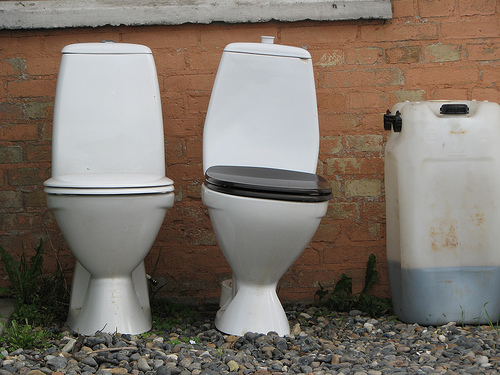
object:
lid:
[41, 173, 175, 197]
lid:
[204, 164, 336, 198]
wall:
[4, 26, 500, 270]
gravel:
[167, 331, 229, 371]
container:
[384, 95, 500, 327]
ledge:
[133, 10, 220, 29]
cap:
[433, 101, 474, 119]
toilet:
[199, 32, 330, 342]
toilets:
[43, 39, 175, 338]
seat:
[198, 165, 330, 341]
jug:
[379, 97, 500, 327]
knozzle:
[382, 108, 402, 133]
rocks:
[330, 354, 340, 365]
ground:
[0, 302, 500, 375]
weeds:
[0, 229, 49, 314]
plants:
[0, 239, 48, 305]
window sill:
[0, 0, 391, 35]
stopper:
[438, 102, 469, 116]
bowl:
[198, 164, 332, 286]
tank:
[45, 40, 169, 171]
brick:
[330, 157, 382, 177]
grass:
[153, 296, 200, 322]